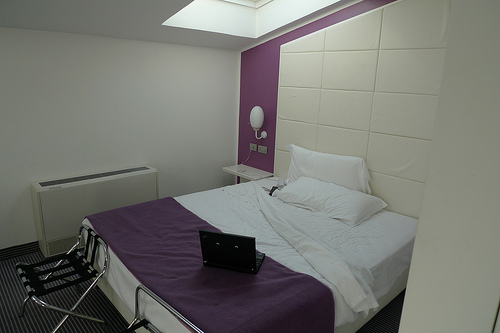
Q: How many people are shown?
A: None.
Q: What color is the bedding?
A: Purple and white.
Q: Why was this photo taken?
A: To show the room.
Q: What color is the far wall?
A: White.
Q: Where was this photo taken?
A: Inside in a room.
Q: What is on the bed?
A: A laptop.